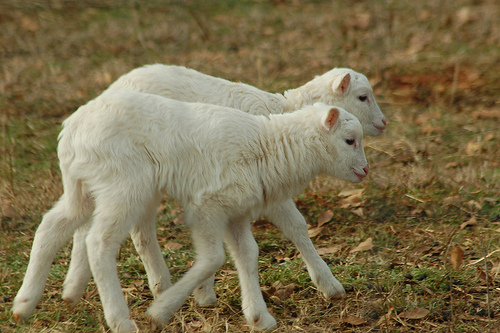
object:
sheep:
[9, 88, 369, 332]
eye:
[343, 138, 355, 146]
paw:
[238, 311, 278, 331]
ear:
[320, 106, 342, 133]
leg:
[84, 198, 151, 333]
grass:
[0, 1, 498, 332]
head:
[313, 101, 371, 185]